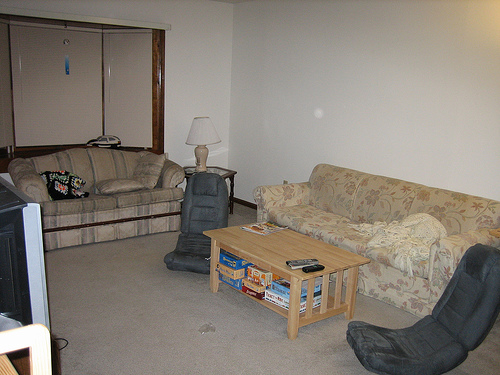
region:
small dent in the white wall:
[303, 91, 345, 133]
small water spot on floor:
[171, 308, 224, 344]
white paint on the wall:
[260, 47, 437, 130]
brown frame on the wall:
[140, 30, 165, 122]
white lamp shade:
[183, 106, 235, 157]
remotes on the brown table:
[270, 246, 335, 299]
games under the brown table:
[200, 236, 347, 329]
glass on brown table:
[168, 157, 230, 189]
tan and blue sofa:
[8, 132, 219, 264]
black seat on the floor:
[142, 157, 252, 284]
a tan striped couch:
[4, 136, 188, 251]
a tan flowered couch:
[249, 156, 496, 327]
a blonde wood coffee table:
[199, 210, 370, 342]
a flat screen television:
[0, 179, 57, 368]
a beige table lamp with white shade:
[180, 114, 222, 172]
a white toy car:
[85, 131, 120, 151]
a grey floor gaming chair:
[166, 170, 229, 275]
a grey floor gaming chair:
[345, 241, 499, 373]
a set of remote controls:
[281, 254, 324, 278]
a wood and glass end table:
[176, 161, 238, 218]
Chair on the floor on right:
[322, 236, 497, 373]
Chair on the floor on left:
[180, 166, 220, 288]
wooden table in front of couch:
[207, 200, 362, 338]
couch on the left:
[0, 122, 196, 243]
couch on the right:
[266, 131, 493, 322]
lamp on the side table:
[177, 108, 230, 193]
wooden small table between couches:
[177, 161, 249, 224]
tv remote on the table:
[300, 260, 325, 277]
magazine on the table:
[244, 210, 289, 245]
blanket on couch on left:
[24, 162, 106, 209]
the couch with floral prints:
[256, 147, 472, 270]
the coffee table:
[206, 221, 347, 336]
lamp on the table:
[180, 104, 230, 169]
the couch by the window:
[19, 147, 186, 247]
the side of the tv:
[1, 167, 68, 374]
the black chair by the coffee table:
[161, 172, 226, 271]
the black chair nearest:
[356, 222, 490, 374]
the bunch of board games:
[221, 254, 288, 308]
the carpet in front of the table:
[81, 271, 173, 338]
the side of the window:
[149, 26, 166, 158]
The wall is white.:
[179, 7, 498, 189]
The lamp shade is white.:
[177, 107, 225, 152]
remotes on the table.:
[276, 252, 323, 280]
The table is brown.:
[196, 212, 370, 341]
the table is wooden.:
[197, 213, 362, 338]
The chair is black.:
[346, 236, 498, 363]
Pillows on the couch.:
[92, 147, 182, 202]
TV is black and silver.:
[2, 164, 48, 356]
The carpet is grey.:
[38, 235, 346, 371]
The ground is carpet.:
[41, 240, 370, 374]